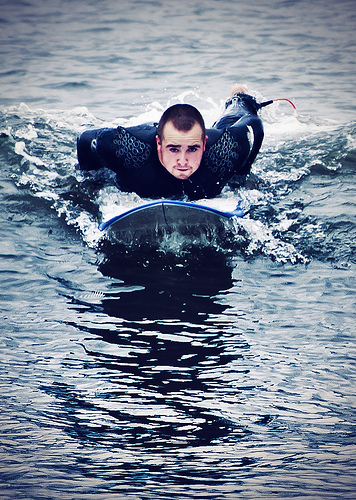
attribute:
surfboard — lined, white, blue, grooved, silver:
[99, 195, 232, 251]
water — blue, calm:
[3, 1, 355, 498]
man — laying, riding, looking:
[74, 90, 264, 205]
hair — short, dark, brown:
[156, 103, 207, 145]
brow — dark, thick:
[165, 142, 185, 150]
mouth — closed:
[172, 165, 191, 173]